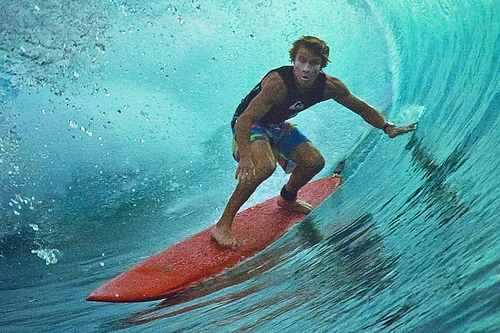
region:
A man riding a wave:
[38, 25, 441, 310]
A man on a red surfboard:
[84, 33, 423, 308]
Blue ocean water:
[369, 156, 494, 312]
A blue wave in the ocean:
[358, 1, 490, 331]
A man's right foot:
[204, 211, 239, 258]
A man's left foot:
[275, 183, 316, 215]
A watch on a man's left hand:
[378, 111, 396, 142]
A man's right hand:
[233, 152, 261, 192]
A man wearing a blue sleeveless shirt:
[196, 31, 426, 252]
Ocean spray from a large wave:
[11, 8, 122, 138]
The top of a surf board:
[167, 253, 192, 278]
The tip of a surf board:
[85, 295, 103, 301]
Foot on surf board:
[213, 229, 238, 251]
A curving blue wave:
[394, 189, 481, 266]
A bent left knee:
[309, 157, 323, 168]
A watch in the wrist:
[388, 121, 395, 125]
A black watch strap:
[385, 127, 388, 128]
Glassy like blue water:
[119, 42, 194, 112]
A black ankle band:
[280, 191, 295, 201]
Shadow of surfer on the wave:
[323, 234, 376, 266]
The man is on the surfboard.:
[148, 65, 419, 218]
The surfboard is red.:
[67, 212, 328, 289]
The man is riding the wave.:
[128, 30, 430, 260]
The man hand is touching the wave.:
[379, 57, 458, 155]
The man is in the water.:
[161, 20, 441, 270]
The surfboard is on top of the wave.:
[80, 211, 376, 290]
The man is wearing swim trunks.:
[233, 117, 310, 162]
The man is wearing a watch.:
[371, 87, 398, 147]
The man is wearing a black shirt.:
[267, 54, 340, 141]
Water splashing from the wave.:
[32, 27, 217, 207]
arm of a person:
[215, 75, 284, 187]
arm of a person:
[330, 77, 420, 144]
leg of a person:
[197, 132, 279, 253]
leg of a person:
[267, 119, 326, 216]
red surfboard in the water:
[79, 148, 349, 315]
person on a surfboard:
[58, 24, 427, 316]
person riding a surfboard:
[69, 33, 431, 311]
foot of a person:
[204, 219, 243, 251]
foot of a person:
[270, 190, 319, 217]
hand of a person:
[232, 150, 261, 185]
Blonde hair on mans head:
[304, 35, 324, 50]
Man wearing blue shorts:
[290, 134, 300, 146]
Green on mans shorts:
[251, 135, 258, 141]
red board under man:
[159, 244, 182, 272]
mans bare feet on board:
[210, 226, 245, 251]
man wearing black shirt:
[287, 75, 297, 94]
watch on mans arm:
[384, 114, 394, 133]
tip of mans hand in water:
[402, 117, 423, 138]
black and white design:
[291, 94, 308, 115]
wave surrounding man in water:
[360, 20, 462, 64]